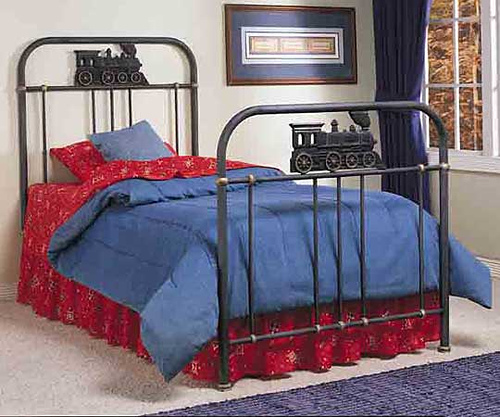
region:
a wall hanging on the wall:
[220, 8, 357, 85]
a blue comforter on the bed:
[47, 163, 492, 381]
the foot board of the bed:
[212, 100, 450, 387]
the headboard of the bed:
[17, 37, 198, 227]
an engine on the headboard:
[72, 39, 147, 88]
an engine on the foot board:
[289, 109, 384, 175]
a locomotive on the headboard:
[72, 44, 149, 87]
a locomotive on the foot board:
[291, 108, 381, 175]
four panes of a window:
[427, 22, 485, 157]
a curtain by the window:
[375, 10, 431, 220]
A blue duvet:
[153, 205, 199, 256]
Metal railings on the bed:
[219, 163, 375, 309]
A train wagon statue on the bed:
[287, 118, 376, 170]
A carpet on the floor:
[399, 368, 480, 408]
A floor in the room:
[27, 327, 76, 395]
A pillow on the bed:
[102, 124, 194, 174]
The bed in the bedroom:
[12, 30, 469, 410]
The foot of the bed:
[195, 95, 460, 385]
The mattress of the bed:
[42, 131, 408, 361]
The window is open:
[415, 5, 492, 165]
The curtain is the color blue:
[370, 1, 435, 212]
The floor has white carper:
[15, 330, 150, 410]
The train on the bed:
[67, 35, 152, 86]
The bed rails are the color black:
[216, 122, 451, 327]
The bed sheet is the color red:
[25, 196, 78, 303]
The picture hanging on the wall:
[217, 4, 372, 96]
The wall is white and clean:
[53, 0, 194, 45]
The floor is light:
[21, 334, 176, 392]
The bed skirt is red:
[69, 290, 443, 372]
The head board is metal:
[19, 10, 244, 135]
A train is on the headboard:
[31, 44, 172, 90]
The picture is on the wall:
[191, 1, 393, 101]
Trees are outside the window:
[416, 45, 496, 137]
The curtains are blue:
[369, 8, 457, 259]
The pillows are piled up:
[49, 120, 202, 193]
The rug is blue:
[236, 387, 351, 414]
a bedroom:
[1, 10, 491, 409]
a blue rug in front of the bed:
[191, 362, 451, 415]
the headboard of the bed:
[24, 47, 207, 173]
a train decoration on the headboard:
[74, 55, 161, 92]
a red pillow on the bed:
[64, 133, 106, 169]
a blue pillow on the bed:
[95, 119, 157, 154]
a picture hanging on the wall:
[233, 8, 348, 81]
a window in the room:
[425, 5, 498, 155]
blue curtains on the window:
[373, 5, 436, 193]